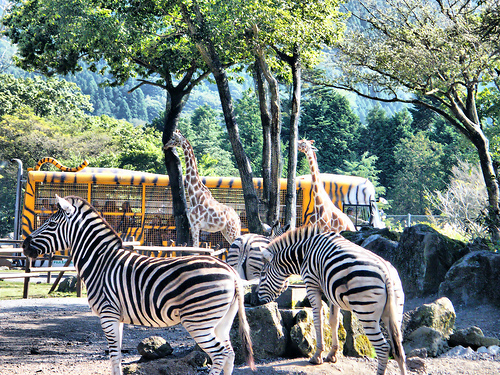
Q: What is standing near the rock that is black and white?
A: Zebra.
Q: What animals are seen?
A: Three zebras and two giraffes.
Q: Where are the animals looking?
A: To their left.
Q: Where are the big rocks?
A: In the enclosure near the animals.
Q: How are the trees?
A: Big and green trees.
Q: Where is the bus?
A: On the road on the other side of the enclosure fence.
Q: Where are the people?
A: Inside the tour bus.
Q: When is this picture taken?
A: During daytime.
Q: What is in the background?
A: Large green trees.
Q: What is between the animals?
A: Rocks.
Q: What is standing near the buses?
A: Giraffes.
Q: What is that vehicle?
A: A bus.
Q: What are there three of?
A: Zebras.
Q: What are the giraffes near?
A: Bus.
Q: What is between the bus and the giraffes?
A: A fence.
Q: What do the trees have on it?
A: Leaves.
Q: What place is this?
A: Zoo.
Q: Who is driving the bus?
A: Man.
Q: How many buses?
A: One.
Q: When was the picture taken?
A: Daytime.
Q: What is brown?
A: Giraffes.